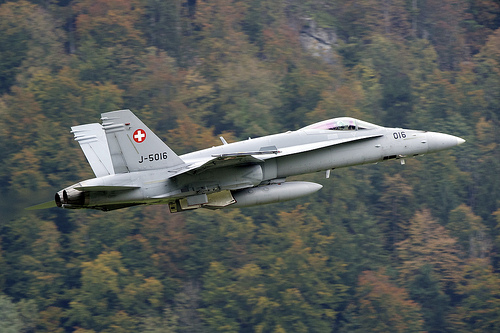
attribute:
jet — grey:
[34, 104, 479, 200]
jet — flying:
[21, 103, 469, 217]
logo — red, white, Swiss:
[131, 126, 148, 143]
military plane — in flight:
[51, 107, 466, 208]